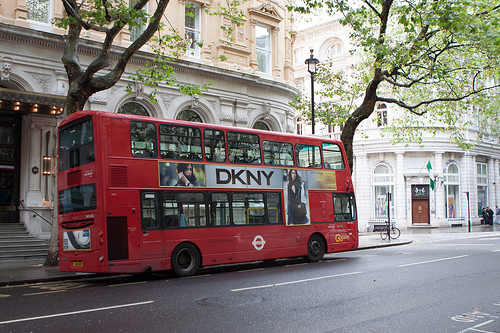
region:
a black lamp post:
[304, 53, 322, 129]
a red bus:
[58, 105, 368, 272]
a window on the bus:
[131, 189, 289, 228]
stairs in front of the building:
[5, 200, 53, 282]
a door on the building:
[413, 182, 428, 224]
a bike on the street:
[376, 219, 406, 240]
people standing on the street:
[479, 208, 496, 225]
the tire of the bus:
[306, 233, 330, 258]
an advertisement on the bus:
[154, 158, 341, 190]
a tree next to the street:
[333, 4, 495, 161]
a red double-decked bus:
[47, 112, 363, 281]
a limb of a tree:
[62, 22, 81, 76]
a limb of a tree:
[82, 34, 113, 73]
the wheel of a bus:
[170, 239, 200, 276]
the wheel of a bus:
[303, 231, 326, 262]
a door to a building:
[409, 180, 431, 229]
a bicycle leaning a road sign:
[377, 219, 402, 241]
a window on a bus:
[125, 117, 160, 161]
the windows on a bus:
[159, 189, 283, 228]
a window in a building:
[252, 19, 274, 73]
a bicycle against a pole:
[379, 216, 415, 241]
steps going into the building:
[15, 198, 56, 285]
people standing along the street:
[476, 198, 497, 240]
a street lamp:
[303, 43, 335, 140]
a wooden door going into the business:
[405, 169, 440, 242]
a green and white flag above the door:
[416, 155, 442, 192]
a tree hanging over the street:
[333, 15, 498, 144]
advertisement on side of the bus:
[136, 155, 346, 227]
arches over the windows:
[113, 101, 299, 136]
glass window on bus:
[128, 118, 158, 159]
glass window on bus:
[157, 122, 200, 157]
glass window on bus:
[204, 128, 225, 161]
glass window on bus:
[225, 128, 259, 164]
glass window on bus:
[262, 137, 294, 163]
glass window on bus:
[296, 142, 323, 164]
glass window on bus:
[139, 191, 158, 224]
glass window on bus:
[333, 195, 351, 220]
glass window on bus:
[56, 186, 98, 210]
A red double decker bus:
[50, 108, 362, 282]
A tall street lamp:
[302, 47, 321, 137]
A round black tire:
[168, 239, 205, 277]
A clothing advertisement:
[152, 154, 312, 231]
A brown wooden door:
[405, 181, 434, 223]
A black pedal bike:
[379, 218, 402, 243]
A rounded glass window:
[438, 158, 464, 221]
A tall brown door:
[0, 95, 27, 225]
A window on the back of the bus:
[52, 110, 98, 175]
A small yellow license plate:
[70, 257, 85, 269]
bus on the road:
[48, 105, 380, 288]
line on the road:
[220, 251, 365, 313]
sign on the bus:
[143, 152, 352, 225]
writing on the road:
[441, 300, 497, 330]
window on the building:
[248, 22, 277, 73]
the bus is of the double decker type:
[51, 108, 360, 278]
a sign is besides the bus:
[157, 158, 337, 220]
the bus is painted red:
[47, 109, 359, 272]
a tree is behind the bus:
[53, 0, 172, 242]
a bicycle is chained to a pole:
[381, 218, 398, 239]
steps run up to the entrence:
[1, 214, 53, 264]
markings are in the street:
[2, 228, 493, 330]